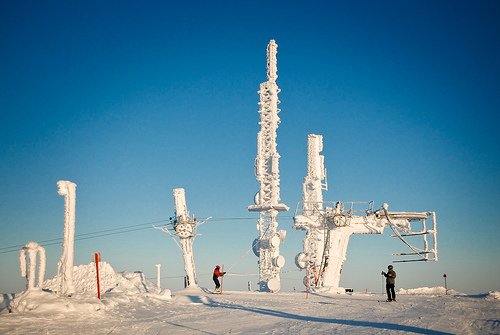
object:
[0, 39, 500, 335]
snow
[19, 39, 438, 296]
items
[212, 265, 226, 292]
people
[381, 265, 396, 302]
skiing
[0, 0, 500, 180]
sky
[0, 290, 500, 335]
ground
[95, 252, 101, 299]
pole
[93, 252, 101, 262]
sign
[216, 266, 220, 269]
hat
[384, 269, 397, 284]
coat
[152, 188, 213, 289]
structure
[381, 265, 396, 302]
man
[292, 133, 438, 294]
equipment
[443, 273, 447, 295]
pole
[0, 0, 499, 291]
air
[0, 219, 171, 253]
power line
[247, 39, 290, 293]
snowy structure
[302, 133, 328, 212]
pole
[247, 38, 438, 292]
structures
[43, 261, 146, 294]
pile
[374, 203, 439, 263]
lift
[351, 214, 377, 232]
ice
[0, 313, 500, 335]
shadow